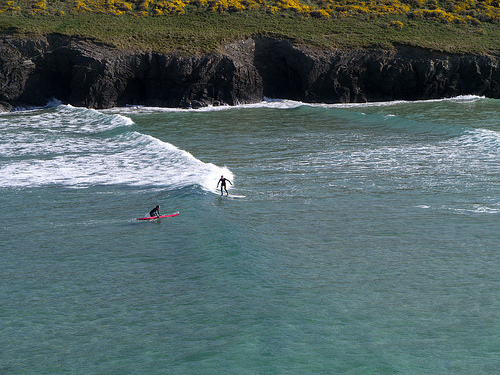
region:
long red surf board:
[136, 212, 181, 224]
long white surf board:
[208, 188, 246, 203]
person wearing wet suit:
[148, 203, 162, 220]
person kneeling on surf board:
[134, 204, 179, 222]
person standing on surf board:
[213, 174, 246, 205]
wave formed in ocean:
[64, 107, 235, 195]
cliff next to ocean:
[4, 29, 499, 114]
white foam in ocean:
[3, 150, 143, 189]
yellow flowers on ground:
[1, 1, 496, 29]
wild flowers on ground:
[2, 2, 497, 31]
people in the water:
[78, 152, 259, 257]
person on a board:
[116, 190, 186, 242]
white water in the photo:
[51, 125, 156, 206]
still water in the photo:
[225, 206, 390, 307]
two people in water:
[75, 157, 261, 267]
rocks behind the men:
[197, 33, 374, 109]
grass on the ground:
[158, 12, 224, 42]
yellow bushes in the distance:
[63, 2, 208, 35]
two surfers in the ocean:
[33, 118, 256, 230]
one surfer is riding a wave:
[158, 135, 253, 202]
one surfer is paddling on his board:
[130, 199, 190, 224]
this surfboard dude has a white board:
[208, 171, 250, 203]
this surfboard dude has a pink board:
[129, 198, 187, 225]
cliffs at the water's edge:
[3, 23, 495, 121]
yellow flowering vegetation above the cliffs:
[21, 0, 498, 29]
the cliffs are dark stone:
[3, 30, 496, 105]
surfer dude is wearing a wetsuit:
[207, 173, 252, 200]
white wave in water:
[204, 156, 221, 179]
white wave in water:
[155, 140, 201, 177]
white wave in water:
[56, 164, 87, 194]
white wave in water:
[32, 143, 46, 155]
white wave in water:
[52, 103, 73, 140]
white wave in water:
[39, 135, 78, 165]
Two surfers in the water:
[141, 175, 246, 220]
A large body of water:
[257, 180, 455, 340]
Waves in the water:
[30, 121, 190, 191]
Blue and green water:
[146, 242, 461, 368]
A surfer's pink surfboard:
[139, 215, 184, 221]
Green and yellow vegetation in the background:
[53, 3, 274, 45]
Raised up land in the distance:
[24, 29, 471, 85]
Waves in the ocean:
[16, 120, 176, 188]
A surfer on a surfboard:
[140, 205, 181, 218]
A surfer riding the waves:
[213, 174, 248, 202]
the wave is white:
[130, 155, 160, 170]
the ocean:
[330, 240, 400, 256]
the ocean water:
[292, 305, 354, 362]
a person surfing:
[216, 171, 235, 200]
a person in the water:
[143, 200, 169, 216]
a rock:
[301, 56, 341, 96]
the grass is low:
[321, 8, 368, 45]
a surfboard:
[138, 213, 178, 220]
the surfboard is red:
[138, 212, 178, 219]